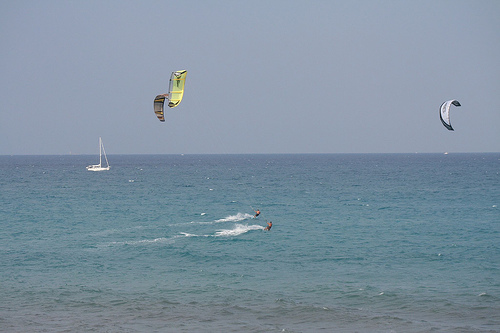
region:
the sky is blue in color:
[298, 43, 377, 111]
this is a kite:
[153, 62, 191, 114]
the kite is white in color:
[438, 91, 453, 127]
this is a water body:
[335, 146, 483, 306]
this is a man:
[265, 211, 283, 233]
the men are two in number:
[234, 186, 299, 247]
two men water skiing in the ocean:
[247, 206, 272, 231]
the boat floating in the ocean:
[86, 135, 109, 173]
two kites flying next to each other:
[151, 68, 188, 121]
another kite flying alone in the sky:
[439, 98, 459, 128]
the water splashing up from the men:
[219, 210, 260, 240]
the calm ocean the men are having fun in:
[4, 158, 499, 332]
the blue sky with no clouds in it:
[3, 4, 499, 154]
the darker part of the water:
[3, 297, 481, 332]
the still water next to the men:
[278, 158, 493, 286]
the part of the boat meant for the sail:
[96, 136, 108, 166]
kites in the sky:
[125, 22, 472, 141]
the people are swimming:
[205, 209, 281, 246]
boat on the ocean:
[70, 123, 116, 180]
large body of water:
[350, 215, 411, 313]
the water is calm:
[98, 262, 167, 297]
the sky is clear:
[287, 38, 330, 135]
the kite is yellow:
[167, 66, 189, 100]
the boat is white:
[82, 161, 107, 175]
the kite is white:
[427, 93, 456, 131]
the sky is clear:
[286, 43, 398, 100]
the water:
[326, 242, 401, 302]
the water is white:
[227, 224, 241, 235]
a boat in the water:
[86, 142, 118, 174]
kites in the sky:
[164, 69, 195, 106]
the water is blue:
[342, 262, 422, 304]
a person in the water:
[264, 219, 279, 232]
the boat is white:
[84, 159, 110, 171]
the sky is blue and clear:
[253, 74, 324, 128]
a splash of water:
[228, 226, 250, 234]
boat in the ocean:
[83, 134, 110, 175]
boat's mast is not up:
[82, 131, 112, 173]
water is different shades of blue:
[305, 151, 388, 317]